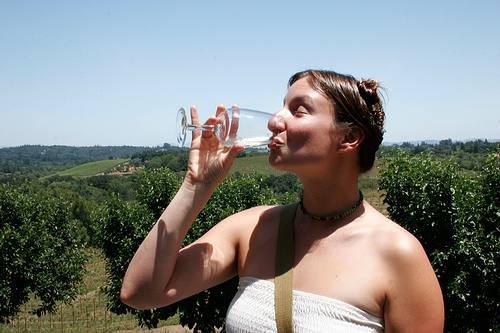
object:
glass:
[176, 109, 278, 151]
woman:
[117, 69, 448, 333]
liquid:
[222, 136, 274, 148]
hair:
[287, 68, 388, 174]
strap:
[274, 204, 295, 332]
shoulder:
[223, 200, 301, 241]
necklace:
[299, 189, 364, 222]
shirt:
[223, 274, 387, 333]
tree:
[3, 142, 500, 332]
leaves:
[482, 205, 487, 210]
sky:
[1, 2, 499, 148]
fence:
[2, 291, 113, 331]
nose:
[266, 108, 286, 133]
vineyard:
[0, 141, 499, 333]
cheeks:
[288, 118, 323, 156]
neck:
[294, 172, 360, 217]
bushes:
[2, 153, 500, 332]